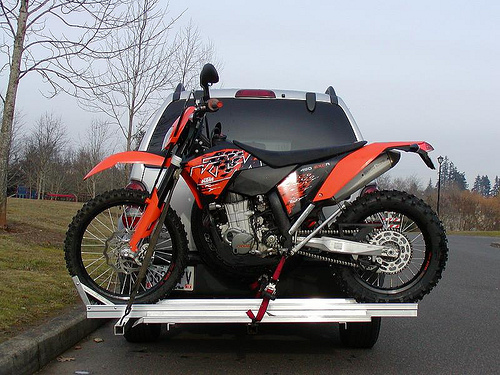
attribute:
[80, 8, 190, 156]
tree — baren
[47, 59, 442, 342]
motorcycle — dirt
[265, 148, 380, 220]
tank — gas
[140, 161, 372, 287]
bike — dirt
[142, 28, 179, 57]
leaves — brown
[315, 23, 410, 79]
day — overcast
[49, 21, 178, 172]
view — outdoor, late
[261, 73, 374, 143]
suv — silver, hauling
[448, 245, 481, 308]
rainswept — asphalt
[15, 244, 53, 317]
grass — patchy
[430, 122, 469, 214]
post — old, evergreen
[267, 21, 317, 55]
sky — blue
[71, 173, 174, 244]
tire — black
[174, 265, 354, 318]
bumper — metal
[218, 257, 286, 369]
strap — red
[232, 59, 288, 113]
light — brake, black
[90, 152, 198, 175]
fender — red